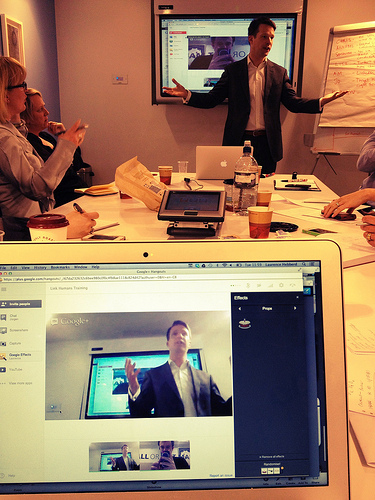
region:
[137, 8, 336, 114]
a portable projection screen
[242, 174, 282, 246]
a few disposable coffee cups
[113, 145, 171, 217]
a white paper bag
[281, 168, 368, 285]
a few papers and pens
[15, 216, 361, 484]
a powered on laptop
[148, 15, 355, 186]
a man wearing a suit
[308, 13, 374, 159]
a large white paper display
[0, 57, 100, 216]
a few women watching a presentation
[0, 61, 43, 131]
a woman wearing glasses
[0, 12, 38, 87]
a framed piece of artwork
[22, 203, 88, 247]
coffee cup has lid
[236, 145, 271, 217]
bottle on the table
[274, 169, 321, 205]
clipboard on the table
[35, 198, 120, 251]
person writing on paper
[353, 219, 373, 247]
man wearing a wedding band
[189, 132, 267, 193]
apple is the brand of laptop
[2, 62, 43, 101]
woman wearing glasses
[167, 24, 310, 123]
screen behind the speaker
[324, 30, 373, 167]
easel for the speech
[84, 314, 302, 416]
speaker on the monitor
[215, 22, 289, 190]
man stands at white board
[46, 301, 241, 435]
man appears on laptop screen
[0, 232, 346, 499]
laptop is white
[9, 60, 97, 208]
people talking to presenter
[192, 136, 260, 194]
man stands in front of white laptop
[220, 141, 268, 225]
clear bottle of water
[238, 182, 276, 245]
small cup of coffee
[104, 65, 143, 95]
small white air conditioning unit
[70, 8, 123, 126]
wall left of screen is white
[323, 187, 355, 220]
person has ring on finger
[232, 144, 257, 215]
plastic bottle sitting on table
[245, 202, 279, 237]
paper cup sitting on table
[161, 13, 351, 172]
man in suit giving presentation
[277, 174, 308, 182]
ink pen lying on papers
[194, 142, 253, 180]
silver computer on table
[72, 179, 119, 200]
open book lying on table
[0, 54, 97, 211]
two women listening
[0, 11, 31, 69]
picture frame hanging on wall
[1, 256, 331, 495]
computer screen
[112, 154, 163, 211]
brown open bag on table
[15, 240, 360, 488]
a man on the computer screen.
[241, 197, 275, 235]
a cup on the table.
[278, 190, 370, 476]
papers are all over the table.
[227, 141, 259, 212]
a bottle of water.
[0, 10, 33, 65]
a picture is on the wall.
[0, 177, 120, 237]
a woman is writing on a note pad.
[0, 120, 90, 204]
a woman is wearing a grey jacket.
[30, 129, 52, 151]
a woman is wearing a black jacket.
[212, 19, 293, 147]
a man is wearing a black jacket.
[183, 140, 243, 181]
the apple laptop is sitting on the table.